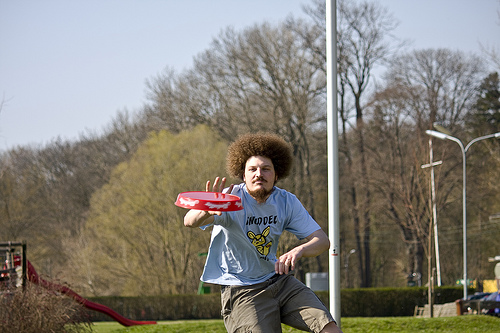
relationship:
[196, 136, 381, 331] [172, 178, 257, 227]
boy with frisbee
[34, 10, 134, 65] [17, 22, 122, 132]
cloud in sky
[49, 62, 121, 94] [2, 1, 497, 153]
white clouds in blue sky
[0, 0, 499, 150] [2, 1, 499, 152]
cloud in blue sky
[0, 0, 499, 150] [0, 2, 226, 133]
cloud in sky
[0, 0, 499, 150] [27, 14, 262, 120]
cloud in sky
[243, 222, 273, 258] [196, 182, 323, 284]
cartoon character on tshirt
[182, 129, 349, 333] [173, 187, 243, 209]
boy catching frisbee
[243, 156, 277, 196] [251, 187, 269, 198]
face with goatee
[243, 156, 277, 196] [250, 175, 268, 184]
face with mustache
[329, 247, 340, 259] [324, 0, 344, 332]
sticker on pole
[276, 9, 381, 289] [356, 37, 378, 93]
tree with branches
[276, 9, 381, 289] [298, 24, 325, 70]
tree with branches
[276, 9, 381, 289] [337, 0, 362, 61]
tree with branches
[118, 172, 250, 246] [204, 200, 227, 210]
frisbee with shape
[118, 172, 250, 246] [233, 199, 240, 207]
frisbee with shape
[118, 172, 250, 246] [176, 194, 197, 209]
frisbee with shape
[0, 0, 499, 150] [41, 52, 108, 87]
cloud in blue sky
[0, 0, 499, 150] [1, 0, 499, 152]
cloud in sky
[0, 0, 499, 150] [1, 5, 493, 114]
cloud in sky